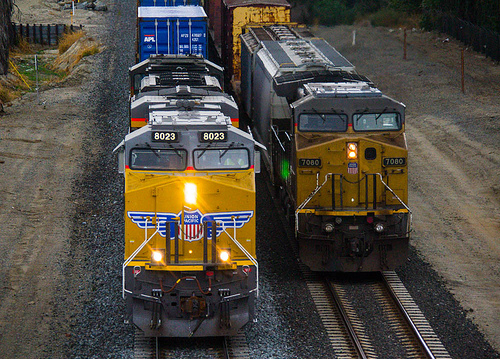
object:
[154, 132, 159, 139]
numbers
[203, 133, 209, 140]
numbers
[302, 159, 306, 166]
number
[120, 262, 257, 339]
cowcatcher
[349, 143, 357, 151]
train light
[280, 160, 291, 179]
light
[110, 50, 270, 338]
engine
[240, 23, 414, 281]
car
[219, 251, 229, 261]
light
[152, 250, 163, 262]
light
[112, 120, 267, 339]
train front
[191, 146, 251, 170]
window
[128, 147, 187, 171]
window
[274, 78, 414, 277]
train engine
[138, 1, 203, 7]
containers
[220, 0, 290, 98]
containers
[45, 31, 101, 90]
debris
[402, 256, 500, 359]
gravel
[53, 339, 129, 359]
train tracks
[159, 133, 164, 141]
numbers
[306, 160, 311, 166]
numbers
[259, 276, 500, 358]
train tracks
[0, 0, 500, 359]
ground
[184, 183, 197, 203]
headlight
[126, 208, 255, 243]
logo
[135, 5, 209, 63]
container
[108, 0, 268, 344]
train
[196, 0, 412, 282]
train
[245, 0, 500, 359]
right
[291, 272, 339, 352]
section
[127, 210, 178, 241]
wings